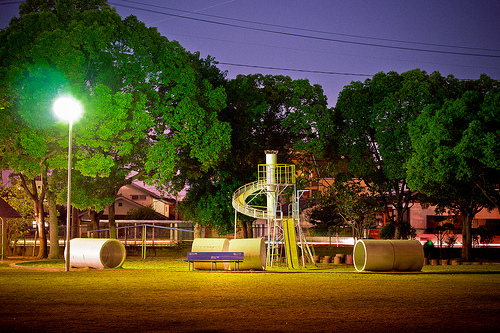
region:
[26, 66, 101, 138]
bright light in park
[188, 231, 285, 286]
large white tubes on ground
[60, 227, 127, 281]
large white tubes on ground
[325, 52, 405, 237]
tall green leafy tree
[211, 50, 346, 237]
tall green leafy tree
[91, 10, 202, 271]
tall green leafy tree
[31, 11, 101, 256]
tall green leafy tree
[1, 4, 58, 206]
tall green leafy tree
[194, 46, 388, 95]
electric wire running above trees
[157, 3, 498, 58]
electric wire running above trees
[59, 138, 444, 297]
a playground is here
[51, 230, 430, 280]
some PVC pipe tubes used for play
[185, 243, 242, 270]
a blue part bench sits next to the play ground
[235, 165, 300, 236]
a slide is on the structure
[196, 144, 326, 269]
a structure is in the center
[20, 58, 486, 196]
a few trees surround the play area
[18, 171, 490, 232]
homes can be seen through the trees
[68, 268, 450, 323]
the ground is covered in green grass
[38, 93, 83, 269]
the light is turned on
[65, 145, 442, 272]
the play ground appears to be made of recycled materials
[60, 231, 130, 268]
tube on a playground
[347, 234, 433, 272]
tube on a playground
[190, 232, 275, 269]
tube on a playground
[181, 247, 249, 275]
purple bench on a playground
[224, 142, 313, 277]
large slide on a playground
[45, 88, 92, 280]
light on a pole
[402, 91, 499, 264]
tree with green leaves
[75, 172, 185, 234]
house near a playground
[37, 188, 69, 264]
trunk of a tree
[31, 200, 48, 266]
trunk of a tree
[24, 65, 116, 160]
lamppost with green glow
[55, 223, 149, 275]
large cyndrical tube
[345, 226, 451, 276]
large split cyndrical tube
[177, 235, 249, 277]
purple/blue colored bench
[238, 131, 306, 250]
spiraled stairs around pole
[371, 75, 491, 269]
large green lush tree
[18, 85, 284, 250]
large green trees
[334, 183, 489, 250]
some large building in back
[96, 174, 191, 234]
2 story house in back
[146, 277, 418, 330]
brown and green ground